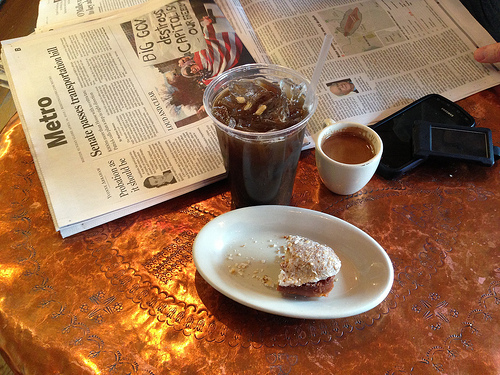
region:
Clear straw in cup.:
[308, 26, 338, 91]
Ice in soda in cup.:
[227, 85, 292, 121]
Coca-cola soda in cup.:
[225, 145, 286, 180]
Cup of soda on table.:
[205, 56, 315, 203]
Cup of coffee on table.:
[315, 105, 380, 195]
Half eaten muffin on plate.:
[265, 225, 340, 300]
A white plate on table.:
[195, 205, 275, 300]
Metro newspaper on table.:
[20, 80, 85, 196]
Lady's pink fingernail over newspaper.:
[465, 45, 495, 70]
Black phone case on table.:
[401, 95, 466, 120]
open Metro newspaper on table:
[1, 7, 496, 173]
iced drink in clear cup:
[216, 65, 298, 190]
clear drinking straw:
[298, 37, 330, 103]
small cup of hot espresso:
[317, 120, 379, 185]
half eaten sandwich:
[283, 235, 333, 299]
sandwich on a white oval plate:
[199, 212, 389, 315]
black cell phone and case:
[381, 97, 480, 168]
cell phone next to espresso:
[382, 94, 490, 171]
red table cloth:
[6, 89, 485, 374]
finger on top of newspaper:
[473, 40, 499, 62]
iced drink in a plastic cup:
[200, 32, 333, 204]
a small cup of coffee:
[313, 117, 382, 197]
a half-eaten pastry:
[277, 231, 339, 297]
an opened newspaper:
[0, 0, 498, 238]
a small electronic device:
[419, 118, 495, 168]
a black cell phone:
[370, 91, 477, 182]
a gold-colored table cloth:
[2, 82, 498, 372]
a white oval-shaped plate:
[192, 203, 394, 321]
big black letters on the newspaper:
[32, 95, 69, 151]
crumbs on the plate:
[222, 238, 275, 288]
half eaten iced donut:
[271, 219, 343, 296]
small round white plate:
[187, 189, 408, 337]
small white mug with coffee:
[305, 109, 387, 184]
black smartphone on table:
[351, 81, 472, 185]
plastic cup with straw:
[205, 64, 324, 205]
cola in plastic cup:
[203, 71, 308, 201]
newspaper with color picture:
[3, 31, 488, 163]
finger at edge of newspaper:
[469, 44, 499, 73]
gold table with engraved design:
[14, 220, 496, 372]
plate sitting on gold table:
[165, 182, 431, 329]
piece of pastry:
[273, 222, 350, 305]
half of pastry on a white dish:
[266, 228, 348, 305]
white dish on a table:
[189, 196, 404, 324]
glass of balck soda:
[194, 54, 319, 199]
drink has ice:
[197, 56, 324, 190]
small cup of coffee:
[313, 109, 390, 203]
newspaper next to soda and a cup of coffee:
[0, 0, 495, 225]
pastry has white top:
[271, 223, 345, 302]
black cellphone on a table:
[368, 82, 481, 187]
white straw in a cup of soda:
[299, 26, 342, 119]